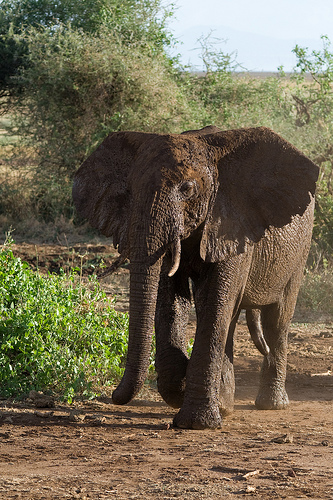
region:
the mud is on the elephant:
[94, 141, 308, 415]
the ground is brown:
[119, 431, 295, 486]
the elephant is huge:
[62, 129, 319, 419]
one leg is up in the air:
[150, 350, 194, 410]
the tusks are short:
[163, 247, 191, 274]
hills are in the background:
[191, 29, 318, 70]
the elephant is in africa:
[7, 30, 329, 467]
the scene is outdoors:
[111, 115, 318, 414]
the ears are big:
[212, 135, 310, 263]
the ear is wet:
[75, 136, 142, 235]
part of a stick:
[224, 447, 256, 483]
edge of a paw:
[186, 406, 211, 436]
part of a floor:
[132, 447, 155, 479]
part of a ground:
[128, 464, 156, 492]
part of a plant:
[61, 375, 89, 408]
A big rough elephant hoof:
[183, 298, 229, 435]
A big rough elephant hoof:
[268, 313, 292, 409]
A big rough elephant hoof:
[160, 313, 188, 395]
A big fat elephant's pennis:
[248, 313, 267, 352]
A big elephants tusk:
[130, 314, 153, 397]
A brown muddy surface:
[67, 430, 199, 488]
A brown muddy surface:
[246, 400, 314, 489]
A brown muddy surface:
[3, 424, 49, 496]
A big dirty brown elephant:
[83, 132, 318, 374]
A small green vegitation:
[5, 253, 120, 397]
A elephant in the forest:
[6, 6, 332, 475]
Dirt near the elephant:
[57, 423, 157, 473]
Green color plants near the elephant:
[6, 261, 89, 362]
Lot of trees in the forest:
[32, 6, 242, 80]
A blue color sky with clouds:
[246, 8, 294, 26]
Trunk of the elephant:
[103, 287, 160, 403]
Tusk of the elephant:
[169, 246, 188, 287]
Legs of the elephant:
[171, 317, 314, 407]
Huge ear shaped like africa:
[218, 129, 332, 255]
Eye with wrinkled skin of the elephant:
[140, 175, 208, 214]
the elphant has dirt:
[137, 127, 194, 182]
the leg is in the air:
[162, 333, 188, 412]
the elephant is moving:
[85, 129, 299, 419]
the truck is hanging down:
[114, 211, 163, 405]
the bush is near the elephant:
[4, 257, 108, 374]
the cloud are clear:
[207, 7, 321, 54]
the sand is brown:
[37, 415, 276, 478]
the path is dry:
[44, 408, 288, 479]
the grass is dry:
[14, 188, 67, 238]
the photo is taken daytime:
[15, 5, 327, 492]